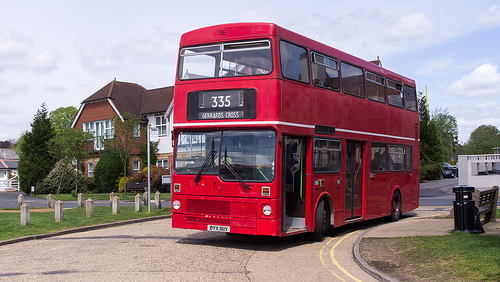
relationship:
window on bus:
[278, 39, 318, 92] [171, 22, 421, 242]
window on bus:
[308, 56, 340, 91] [171, 22, 421, 242]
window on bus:
[345, 65, 366, 98] [171, 22, 421, 242]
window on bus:
[386, 78, 404, 108] [171, 22, 421, 242]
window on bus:
[390, 80, 403, 107] [171, 22, 421, 242]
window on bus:
[402, 83, 415, 110] [171, 22, 421, 242]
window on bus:
[315, 137, 343, 174] [171, 22, 421, 242]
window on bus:
[367, 142, 389, 175] [171, 22, 421, 242]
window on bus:
[388, 146, 405, 169] [171, 22, 421, 242]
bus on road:
[171, 22, 421, 242] [12, 181, 494, 281]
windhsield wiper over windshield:
[194, 151, 218, 183] [166, 127, 277, 182]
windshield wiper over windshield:
[222, 160, 251, 189] [166, 127, 277, 182]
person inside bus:
[375, 153, 388, 169] [171, 22, 421, 242]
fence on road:
[11, 193, 171, 227] [12, 181, 494, 281]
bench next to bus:
[463, 188, 497, 220] [171, 22, 421, 242]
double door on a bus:
[343, 142, 363, 237] [171, 22, 421, 242]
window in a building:
[85, 158, 99, 178] [61, 74, 181, 198]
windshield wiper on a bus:
[182, 128, 214, 178] [171, 22, 421, 242]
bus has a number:
[171, 22, 421, 242] [201, 86, 237, 113]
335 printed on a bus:
[212, 95, 232, 107] [171, 22, 421, 242]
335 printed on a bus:
[206, 88, 235, 115] [171, 22, 421, 242]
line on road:
[308, 206, 418, 280] [1, 163, 484, 281]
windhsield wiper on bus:
[190, 146, 224, 193] [171, 22, 421, 242]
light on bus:
[264, 203, 273, 223] [171, 22, 421, 242]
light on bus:
[263, 205, 272, 216] [172, 17, 415, 255]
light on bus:
[168, 203, 178, 210] [172, 17, 415, 255]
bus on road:
[171, 22, 421, 242] [1, 163, 484, 281]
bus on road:
[172, 17, 415, 255] [1, 163, 484, 281]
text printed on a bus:
[195, 101, 242, 121] [171, 22, 421, 242]